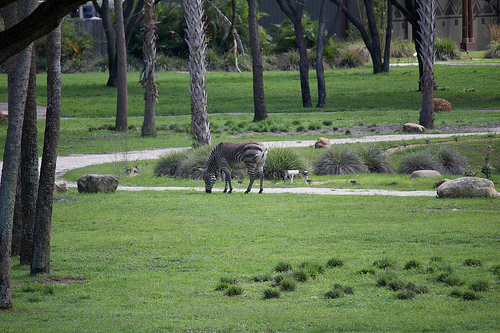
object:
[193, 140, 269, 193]
zebra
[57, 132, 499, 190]
field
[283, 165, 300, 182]
object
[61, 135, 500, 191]
grass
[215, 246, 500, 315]
crab grass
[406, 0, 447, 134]
tree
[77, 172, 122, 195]
rock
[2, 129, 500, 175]
road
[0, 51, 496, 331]
park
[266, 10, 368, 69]
plants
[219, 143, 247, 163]
stripes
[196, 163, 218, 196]
head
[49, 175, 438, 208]
path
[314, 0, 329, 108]
tree trunk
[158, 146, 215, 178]
bush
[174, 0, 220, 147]
palm trees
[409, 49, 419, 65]
light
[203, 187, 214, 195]
mouth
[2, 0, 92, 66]
branch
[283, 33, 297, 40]
leaves